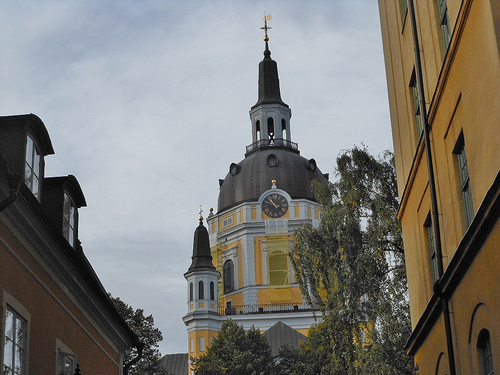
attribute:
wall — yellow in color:
[201, 194, 322, 305]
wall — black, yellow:
[190, 322, 372, 373]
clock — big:
[255, 189, 294, 221]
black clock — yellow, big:
[263, 190, 290, 227]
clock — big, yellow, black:
[258, 190, 290, 221]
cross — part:
[259, 15, 269, 39]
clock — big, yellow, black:
[263, 185, 292, 222]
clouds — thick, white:
[2, 2, 402, 352]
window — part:
[448, 145, 487, 235]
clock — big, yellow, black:
[252, 165, 310, 223]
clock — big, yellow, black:
[254, 183, 295, 220]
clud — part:
[123, 176, 191, 288]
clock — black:
[259, 186, 290, 218]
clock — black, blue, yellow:
[254, 179, 335, 242]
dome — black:
[197, 121, 390, 243]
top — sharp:
[233, 25, 308, 144]